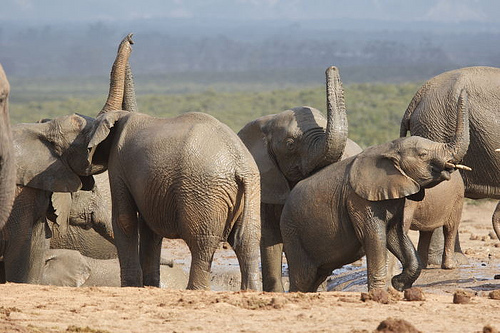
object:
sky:
[0, 3, 498, 65]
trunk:
[303, 65, 349, 176]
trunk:
[445, 87, 469, 164]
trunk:
[95, 33, 133, 115]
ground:
[0, 195, 497, 332]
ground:
[353, 131, 445, 226]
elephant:
[231, 72, 359, 289]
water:
[340, 267, 362, 288]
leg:
[111, 179, 143, 285]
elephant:
[13, 23, 475, 286]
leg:
[351, 210, 403, 318]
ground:
[361, 177, 392, 217]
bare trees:
[275, 84, 480, 304]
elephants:
[0, 36, 499, 308]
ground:
[2, 287, 499, 332]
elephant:
[235, 114, 371, 296]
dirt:
[0, 197, 498, 330]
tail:
[230, 159, 249, 252]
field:
[0, 83, 498, 329]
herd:
[0, 31, 498, 304]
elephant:
[393, 65, 498, 246]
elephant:
[77, 82, 269, 295]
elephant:
[277, 88, 471, 293]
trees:
[2, 18, 498, 83]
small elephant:
[283, 86, 475, 302]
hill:
[4, 12, 499, 77]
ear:
[350, 152, 430, 217]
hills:
[3, 14, 499, 91]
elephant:
[405, 168, 465, 270]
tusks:
[443, 162, 472, 176]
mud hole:
[0, 178, 497, 329]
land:
[0, 90, 498, 330]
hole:
[104, 245, 386, 308]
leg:
[184, 228, 217, 296]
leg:
[227, 207, 270, 299]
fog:
[1, 0, 498, 78]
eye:
[417, 148, 428, 158]